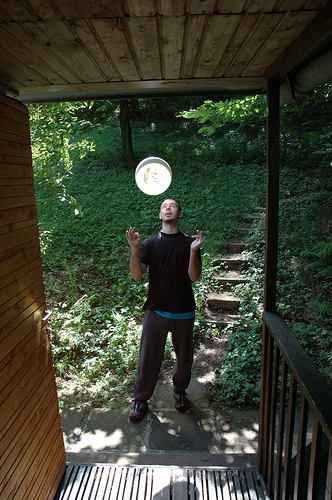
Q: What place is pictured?
A: It is a garden.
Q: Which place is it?
A: It is a garden.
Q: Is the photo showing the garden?
A: Yes, it is showing the garden.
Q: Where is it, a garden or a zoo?
A: It is a garden.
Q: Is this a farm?
A: No, it is a garden.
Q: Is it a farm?
A: No, it is a garden.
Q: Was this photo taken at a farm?
A: No, the picture was taken in a garden.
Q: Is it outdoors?
A: Yes, it is outdoors.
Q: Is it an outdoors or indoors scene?
A: It is outdoors.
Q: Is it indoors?
A: No, it is outdoors.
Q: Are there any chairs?
A: No, there are no chairs.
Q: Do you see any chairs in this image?
A: No, there are no chairs.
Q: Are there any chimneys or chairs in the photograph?
A: No, there are no chairs or chimneys.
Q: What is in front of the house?
A: The porch is in front of the house.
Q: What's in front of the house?
A: The porch is in front of the house.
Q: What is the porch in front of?
A: The porch is in front of the house.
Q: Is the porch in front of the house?
A: Yes, the porch is in front of the house.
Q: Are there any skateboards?
A: No, there are no skateboards.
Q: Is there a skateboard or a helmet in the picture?
A: No, there are no skateboards or helmets.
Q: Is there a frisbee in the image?
A: Yes, there is a frisbee.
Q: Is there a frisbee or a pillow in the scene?
A: Yes, there is a frisbee.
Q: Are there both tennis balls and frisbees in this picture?
A: No, there is a frisbee but no tennis balls.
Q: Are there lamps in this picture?
A: No, there are no lamps.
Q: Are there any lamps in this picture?
A: No, there are no lamps.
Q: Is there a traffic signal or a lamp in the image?
A: No, there are no lamps or traffic lights.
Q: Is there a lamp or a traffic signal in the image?
A: No, there are no lamps or traffic lights.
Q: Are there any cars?
A: No, there are no cars.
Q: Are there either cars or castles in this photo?
A: No, there are no cars or castles.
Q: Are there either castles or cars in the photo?
A: No, there are no cars or castles.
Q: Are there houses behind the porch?
A: Yes, there is a house behind the porch.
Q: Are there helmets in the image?
A: No, there are no helmets.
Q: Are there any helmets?
A: No, there are no helmets.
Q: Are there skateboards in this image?
A: No, there are no skateboards.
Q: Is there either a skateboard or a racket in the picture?
A: No, there are no skateboards or rackets.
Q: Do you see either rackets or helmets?
A: No, there are no helmets or rackets.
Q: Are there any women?
A: No, there are no women.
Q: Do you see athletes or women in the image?
A: No, there are no women or athletes.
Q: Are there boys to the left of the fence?
A: Yes, there is a boy to the left of the fence.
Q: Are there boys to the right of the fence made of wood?
A: No, the boy is to the left of the fence.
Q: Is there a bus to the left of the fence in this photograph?
A: No, there is a boy to the left of the fence.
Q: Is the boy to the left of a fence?
A: Yes, the boy is to the left of a fence.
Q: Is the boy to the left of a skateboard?
A: No, the boy is to the left of a fence.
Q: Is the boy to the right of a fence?
A: No, the boy is to the left of a fence.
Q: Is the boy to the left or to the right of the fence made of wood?
A: The boy is to the left of the fence.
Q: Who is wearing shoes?
A: The boy is wearing shoes.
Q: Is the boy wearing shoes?
A: Yes, the boy is wearing shoes.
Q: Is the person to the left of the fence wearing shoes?
A: Yes, the boy is wearing shoes.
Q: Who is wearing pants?
A: The boy is wearing pants.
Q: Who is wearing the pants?
A: The boy is wearing pants.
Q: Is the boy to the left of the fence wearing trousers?
A: Yes, the boy is wearing trousers.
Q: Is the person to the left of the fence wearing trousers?
A: Yes, the boy is wearing trousers.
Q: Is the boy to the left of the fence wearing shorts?
A: No, the boy is wearing trousers.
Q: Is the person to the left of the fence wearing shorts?
A: No, the boy is wearing trousers.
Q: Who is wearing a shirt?
A: The boy is wearing a shirt.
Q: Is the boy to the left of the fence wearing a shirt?
A: Yes, the boy is wearing a shirt.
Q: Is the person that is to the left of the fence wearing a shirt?
A: Yes, the boy is wearing a shirt.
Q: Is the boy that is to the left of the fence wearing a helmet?
A: No, the boy is wearing a shirt.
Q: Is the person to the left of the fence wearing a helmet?
A: No, the boy is wearing a shirt.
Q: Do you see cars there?
A: No, there are no cars.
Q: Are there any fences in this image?
A: Yes, there is a fence.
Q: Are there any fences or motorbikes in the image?
A: Yes, there is a fence.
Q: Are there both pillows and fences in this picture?
A: No, there is a fence but no pillows.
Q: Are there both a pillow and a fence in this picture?
A: No, there is a fence but no pillows.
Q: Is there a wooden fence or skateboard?
A: Yes, there is a wood fence.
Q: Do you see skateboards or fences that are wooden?
A: Yes, the fence is wooden.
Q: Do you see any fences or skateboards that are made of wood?
A: Yes, the fence is made of wood.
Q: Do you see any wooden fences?
A: Yes, there is a wood fence.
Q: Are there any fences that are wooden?
A: Yes, there is a wood fence.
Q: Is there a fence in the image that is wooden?
A: Yes, there is a fence that is wooden.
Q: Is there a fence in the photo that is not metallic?
A: Yes, there is a wooden fence.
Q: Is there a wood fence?
A: Yes, there is a fence that is made of wood.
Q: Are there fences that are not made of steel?
A: Yes, there is a fence that is made of wood.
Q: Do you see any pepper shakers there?
A: No, there are no pepper shakers.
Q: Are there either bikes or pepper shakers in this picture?
A: No, there are no pepper shakers or bikes.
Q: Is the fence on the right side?
A: Yes, the fence is on the right of the image.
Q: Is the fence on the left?
A: No, the fence is on the right of the image.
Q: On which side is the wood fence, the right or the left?
A: The fence is on the right of the image.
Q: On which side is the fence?
A: The fence is on the right of the image.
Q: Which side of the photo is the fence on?
A: The fence is on the right of the image.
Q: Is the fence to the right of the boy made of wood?
A: Yes, the fence is made of wood.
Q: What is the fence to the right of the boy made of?
A: The fence is made of wood.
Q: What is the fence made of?
A: The fence is made of wood.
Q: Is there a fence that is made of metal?
A: No, there is a fence but it is made of wood.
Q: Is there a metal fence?
A: No, there is a fence but it is made of wood.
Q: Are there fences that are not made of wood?
A: No, there is a fence but it is made of wood.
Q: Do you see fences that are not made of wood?
A: No, there is a fence but it is made of wood.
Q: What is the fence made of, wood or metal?
A: The fence is made of wood.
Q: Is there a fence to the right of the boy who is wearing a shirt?
A: Yes, there is a fence to the right of the boy.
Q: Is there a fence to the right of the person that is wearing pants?
A: Yes, there is a fence to the right of the boy.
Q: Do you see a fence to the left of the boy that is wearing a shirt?
A: No, the fence is to the right of the boy.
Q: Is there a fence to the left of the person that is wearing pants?
A: No, the fence is to the right of the boy.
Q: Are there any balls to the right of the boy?
A: No, there is a fence to the right of the boy.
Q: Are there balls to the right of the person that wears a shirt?
A: No, there is a fence to the right of the boy.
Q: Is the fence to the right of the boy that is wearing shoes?
A: Yes, the fence is to the right of the boy.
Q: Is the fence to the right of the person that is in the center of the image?
A: Yes, the fence is to the right of the boy.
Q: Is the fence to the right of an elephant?
A: No, the fence is to the right of the boy.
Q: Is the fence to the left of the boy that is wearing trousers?
A: No, the fence is to the right of the boy.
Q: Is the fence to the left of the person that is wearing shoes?
A: No, the fence is to the right of the boy.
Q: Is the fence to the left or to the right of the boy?
A: The fence is to the right of the boy.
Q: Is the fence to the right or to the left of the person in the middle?
A: The fence is to the right of the boy.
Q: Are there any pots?
A: No, there are no pots.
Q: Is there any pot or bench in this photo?
A: No, there are no pots or benches.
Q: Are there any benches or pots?
A: No, there are no pots or benches.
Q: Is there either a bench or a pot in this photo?
A: No, there are no pots or benches.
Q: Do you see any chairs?
A: No, there are no chairs.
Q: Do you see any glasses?
A: No, there are no glasses.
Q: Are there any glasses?
A: No, there are no glasses.